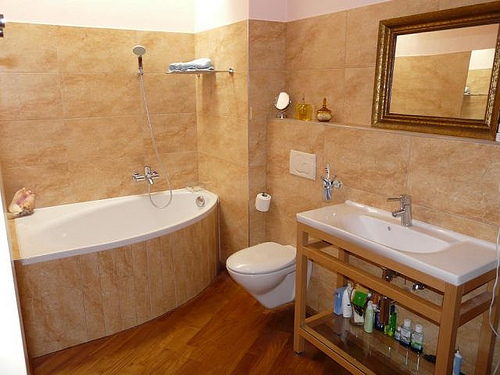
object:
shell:
[8, 186, 37, 224]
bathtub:
[12, 186, 226, 360]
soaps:
[410, 324, 424, 351]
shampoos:
[361, 299, 374, 334]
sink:
[341, 213, 450, 255]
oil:
[295, 93, 312, 121]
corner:
[254, 21, 320, 124]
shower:
[130, 43, 153, 92]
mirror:
[379, 19, 494, 118]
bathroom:
[0, 0, 500, 375]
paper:
[255, 193, 273, 214]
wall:
[0, 0, 500, 375]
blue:
[196, 63, 206, 71]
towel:
[168, 55, 215, 68]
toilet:
[224, 235, 310, 308]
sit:
[228, 239, 298, 274]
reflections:
[386, 23, 500, 120]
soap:
[325, 188, 331, 203]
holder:
[317, 164, 335, 203]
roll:
[252, 190, 273, 211]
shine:
[167, 329, 189, 352]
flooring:
[28, 266, 354, 374]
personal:
[341, 288, 351, 319]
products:
[351, 292, 364, 324]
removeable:
[136, 69, 146, 79]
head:
[131, 43, 145, 77]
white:
[89, 216, 111, 233]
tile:
[172, 266, 192, 285]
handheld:
[136, 57, 142, 77]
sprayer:
[131, 45, 147, 60]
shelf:
[166, 70, 234, 80]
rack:
[199, 67, 235, 80]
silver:
[403, 202, 407, 209]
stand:
[276, 109, 284, 119]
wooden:
[296, 225, 305, 238]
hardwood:
[24, 267, 355, 375]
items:
[362, 298, 375, 335]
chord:
[138, 68, 172, 211]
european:
[225, 236, 314, 311]